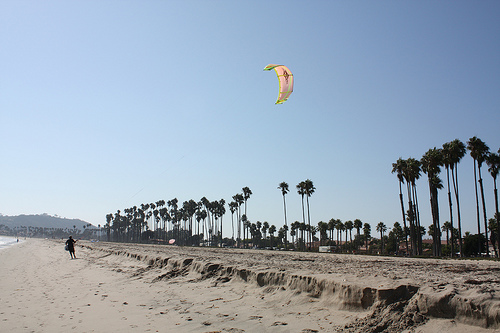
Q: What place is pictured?
A: It is a beach.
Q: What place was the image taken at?
A: It was taken at the beach.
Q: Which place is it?
A: It is a beach.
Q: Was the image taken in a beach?
A: Yes, it was taken in a beach.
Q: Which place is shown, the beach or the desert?
A: It is the beach.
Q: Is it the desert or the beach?
A: It is the beach.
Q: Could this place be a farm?
A: No, it is a beach.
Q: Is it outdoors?
A: Yes, it is outdoors.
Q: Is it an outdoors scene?
A: Yes, it is outdoors.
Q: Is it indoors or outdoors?
A: It is outdoors.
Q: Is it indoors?
A: No, it is outdoors.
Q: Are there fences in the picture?
A: No, there are no fences.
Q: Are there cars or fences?
A: No, there are no fences or cars.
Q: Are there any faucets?
A: No, there are no faucets.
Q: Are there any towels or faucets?
A: No, there are no faucets or towels.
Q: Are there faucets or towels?
A: No, there are no faucets or towels.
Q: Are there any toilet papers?
A: No, there are no toilet papers.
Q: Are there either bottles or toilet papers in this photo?
A: No, there are no toilet papers or bottles.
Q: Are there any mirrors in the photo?
A: No, there are no mirrors.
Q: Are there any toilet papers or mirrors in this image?
A: No, there are no mirrors or toilet papers.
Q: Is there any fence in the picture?
A: No, there are no fences.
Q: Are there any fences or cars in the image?
A: No, there are no fences or cars.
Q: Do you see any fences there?
A: No, there are no fences.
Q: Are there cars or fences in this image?
A: No, there are no fences or cars.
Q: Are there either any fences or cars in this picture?
A: No, there are no fences or cars.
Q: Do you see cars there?
A: No, there are no cars.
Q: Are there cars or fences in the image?
A: No, there are no cars or fences.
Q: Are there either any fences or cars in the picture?
A: No, there are no cars or fences.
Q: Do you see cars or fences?
A: No, there are no cars or fences.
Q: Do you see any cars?
A: No, there are no cars.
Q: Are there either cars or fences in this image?
A: No, there are no cars or fences.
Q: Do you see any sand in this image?
A: Yes, there is sand.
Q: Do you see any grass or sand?
A: Yes, there is sand.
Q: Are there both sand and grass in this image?
A: No, there is sand but no grass.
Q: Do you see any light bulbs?
A: No, there are no light bulbs.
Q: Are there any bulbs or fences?
A: No, there are no bulbs or fences.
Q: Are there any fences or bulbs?
A: No, there are no bulbs or fences.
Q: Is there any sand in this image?
A: Yes, there is sand.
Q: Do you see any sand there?
A: Yes, there is sand.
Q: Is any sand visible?
A: Yes, there is sand.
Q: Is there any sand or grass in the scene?
A: Yes, there is sand.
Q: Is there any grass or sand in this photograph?
A: Yes, there is sand.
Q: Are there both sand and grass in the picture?
A: No, there is sand but no grass.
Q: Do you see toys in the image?
A: No, there are no toys.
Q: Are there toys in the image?
A: No, there are no toys.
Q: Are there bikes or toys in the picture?
A: No, there are no toys or bikes.